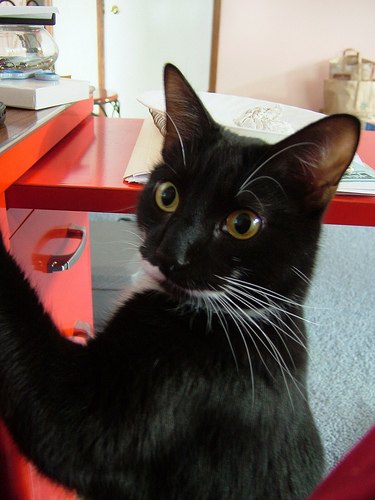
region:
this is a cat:
[27, 55, 299, 314]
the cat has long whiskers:
[180, 269, 306, 362]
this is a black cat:
[89, 325, 263, 440]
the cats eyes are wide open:
[127, 145, 277, 263]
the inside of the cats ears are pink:
[287, 111, 356, 191]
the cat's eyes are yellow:
[153, 178, 315, 291]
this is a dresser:
[22, 213, 125, 346]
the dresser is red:
[24, 220, 75, 303]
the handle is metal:
[33, 209, 101, 293]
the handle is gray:
[41, 226, 103, 282]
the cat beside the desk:
[1, 61, 363, 442]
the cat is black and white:
[0, 48, 345, 498]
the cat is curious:
[17, 55, 373, 487]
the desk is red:
[16, 89, 123, 340]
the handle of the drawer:
[37, 220, 91, 287]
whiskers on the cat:
[186, 276, 300, 347]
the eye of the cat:
[218, 201, 260, 239]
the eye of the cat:
[154, 175, 188, 222]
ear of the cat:
[153, 61, 218, 145]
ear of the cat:
[274, 110, 359, 205]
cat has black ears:
[139, 62, 364, 178]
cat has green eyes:
[146, 177, 256, 243]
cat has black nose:
[146, 222, 179, 264]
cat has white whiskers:
[146, 246, 332, 367]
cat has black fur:
[42, 361, 329, 496]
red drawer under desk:
[8, 209, 101, 347]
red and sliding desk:
[38, 112, 367, 202]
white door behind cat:
[102, 13, 204, 109]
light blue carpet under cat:
[313, 230, 370, 403]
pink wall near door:
[237, 15, 293, 85]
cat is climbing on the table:
[46, 110, 334, 443]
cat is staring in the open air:
[159, 140, 315, 470]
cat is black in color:
[107, 153, 281, 485]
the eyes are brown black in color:
[147, 184, 268, 264]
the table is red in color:
[35, 132, 123, 200]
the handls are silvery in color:
[51, 220, 92, 277]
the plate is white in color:
[245, 91, 294, 138]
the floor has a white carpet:
[309, 297, 371, 387]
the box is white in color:
[17, 81, 95, 109]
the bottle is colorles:
[3, 26, 53, 62]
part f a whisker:
[235, 295, 270, 345]